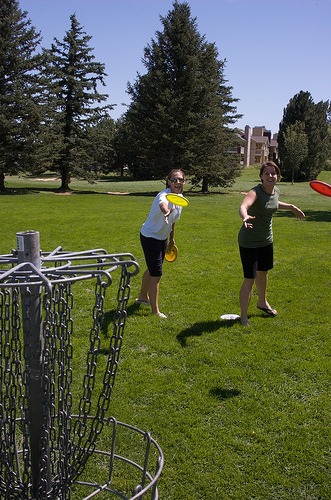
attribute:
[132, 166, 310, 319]
women — playing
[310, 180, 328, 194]
frisbee — flying, red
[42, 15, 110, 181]
pine tree — large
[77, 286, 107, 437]
chain — metal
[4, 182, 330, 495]
grass — lush, green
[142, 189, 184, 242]
shirt — white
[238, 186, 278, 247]
shirt — green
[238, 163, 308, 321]
person — smiling, young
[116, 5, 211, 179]
tree — dark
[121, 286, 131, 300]
chain link — metal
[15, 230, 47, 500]
pole — gray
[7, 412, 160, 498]
basket — metal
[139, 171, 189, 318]
woman — smiling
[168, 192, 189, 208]
disc — yellow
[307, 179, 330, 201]
frisbee — red, flying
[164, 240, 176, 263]
frisbee — yellow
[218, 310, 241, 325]
frisbee — white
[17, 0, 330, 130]
sky — blue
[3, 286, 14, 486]
chain — hanging